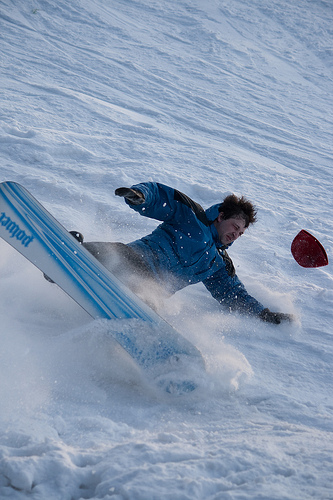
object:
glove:
[262, 308, 297, 326]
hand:
[110, 184, 149, 206]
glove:
[112, 185, 145, 211]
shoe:
[68, 230, 86, 246]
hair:
[220, 191, 259, 228]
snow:
[1, 1, 333, 500]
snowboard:
[0, 179, 209, 406]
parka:
[125, 180, 267, 331]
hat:
[289, 229, 329, 271]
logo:
[0, 211, 37, 250]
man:
[42, 180, 295, 359]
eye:
[231, 224, 239, 231]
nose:
[231, 231, 239, 240]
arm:
[128, 180, 207, 222]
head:
[211, 194, 259, 250]